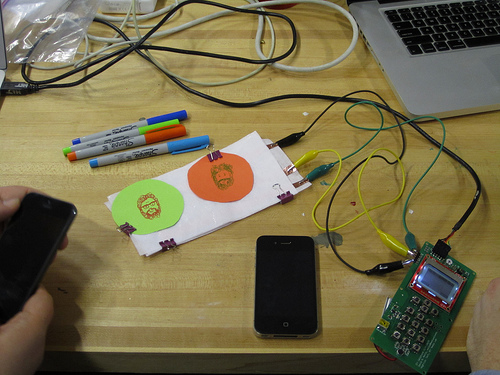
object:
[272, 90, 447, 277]
cord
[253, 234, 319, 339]
cellphone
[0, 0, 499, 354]
counter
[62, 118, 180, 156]
markers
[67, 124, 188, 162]
markers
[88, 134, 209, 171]
markers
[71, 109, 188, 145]
markers